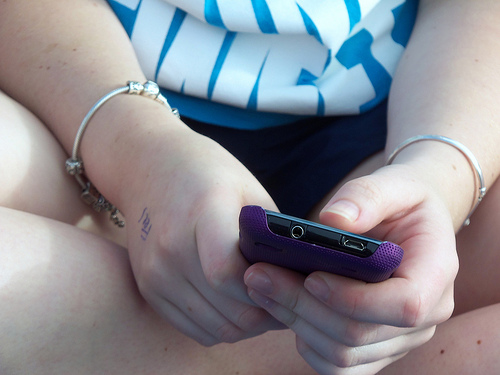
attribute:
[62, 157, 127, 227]
beads — silver 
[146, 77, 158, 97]
bead — silver 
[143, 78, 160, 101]
bead — silver 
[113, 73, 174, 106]
beads — silver 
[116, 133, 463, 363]
hands — woman's 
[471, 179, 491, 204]
bead — silver 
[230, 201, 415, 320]
cellphone — black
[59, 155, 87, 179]
bead — silver 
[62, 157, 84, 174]
bead — silver 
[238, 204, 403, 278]
case — purple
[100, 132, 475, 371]
hands — woman's 